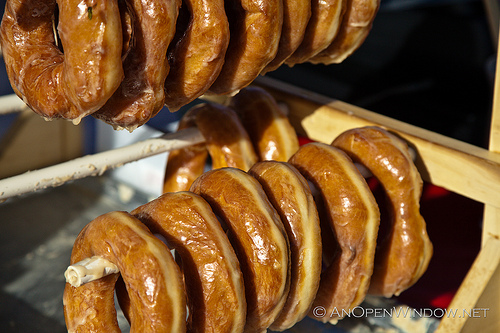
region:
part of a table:
[455, 147, 464, 152]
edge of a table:
[411, 170, 421, 185]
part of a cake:
[233, 240, 245, 259]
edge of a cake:
[199, 263, 226, 290]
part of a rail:
[41, 182, 65, 212]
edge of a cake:
[376, 191, 403, 193]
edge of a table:
[436, 140, 458, 162]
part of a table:
[51, 215, 65, 230]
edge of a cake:
[239, 268, 249, 279]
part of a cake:
[135, 266, 151, 307]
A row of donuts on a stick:
[65, 137, 431, 327]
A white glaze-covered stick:
[0, 118, 205, 203]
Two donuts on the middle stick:
[164, 82, 295, 195]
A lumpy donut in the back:
[365, 134, 441, 299]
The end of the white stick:
[64, 267, 86, 286]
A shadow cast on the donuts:
[157, 60, 328, 142]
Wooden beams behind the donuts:
[262, 51, 498, 331]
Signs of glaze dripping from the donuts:
[47, 109, 149, 135]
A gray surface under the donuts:
[0, 163, 446, 331]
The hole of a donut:
[102, 272, 135, 329]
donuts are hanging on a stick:
[50, 159, 445, 301]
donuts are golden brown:
[117, 142, 431, 295]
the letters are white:
[311, 295, 496, 325]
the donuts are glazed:
[68, 209, 204, 318]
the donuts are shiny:
[38, 186, 297, 311]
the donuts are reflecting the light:
[78, 182, 302, 303]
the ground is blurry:
[4, 170, 132, 241]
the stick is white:
[1, 145, 191, 222]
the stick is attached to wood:
[346, 102, 491, 302]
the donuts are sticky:
[71, 178, 298, 311]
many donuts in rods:
[6, 6, 484, 324]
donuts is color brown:
[48, 205, 187, 331]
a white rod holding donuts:
[3, 118, 268, 195]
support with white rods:
[0, 9, 498, 326]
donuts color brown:
[3, 0, 375, 125]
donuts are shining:
[82, 125, 439, 332]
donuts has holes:
[52, 212, 183, 332]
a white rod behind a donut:
[3, 75, 38, 124]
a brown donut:
[115, 0, 179, 130]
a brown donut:
[174, 0, 230, 100]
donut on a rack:
[75, 213, 161, 332]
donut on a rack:
[141, 188, 238, 332]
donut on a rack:
[207, 164, 284, 331]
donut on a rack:
[264, 158, 318, 331]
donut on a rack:
[297, 141, 371, 331]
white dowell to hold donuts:
[15, 121, 204, 198]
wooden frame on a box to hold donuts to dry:
[293, 88, 498, 328]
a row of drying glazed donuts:
[83, 121, 432, 329]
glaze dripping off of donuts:
[46, 100, 144, 140]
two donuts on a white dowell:
[182, 90, 283, 175]